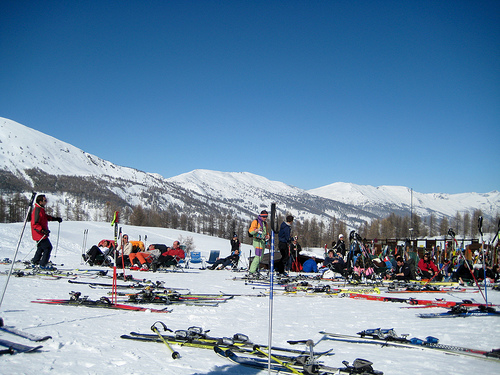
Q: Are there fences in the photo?
A: No, there are no fences.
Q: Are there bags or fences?
A: No, there are no fences or bags.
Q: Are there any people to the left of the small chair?
A: Yes, there is a person to the left of the chair.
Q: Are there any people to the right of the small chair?
A: No, the person is to the left of the chair.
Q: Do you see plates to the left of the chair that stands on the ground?
A: No, there is a person to the left of the chair.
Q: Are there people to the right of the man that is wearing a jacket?
A: Yes, there is a person to the right of the man.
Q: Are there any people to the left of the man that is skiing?
A: No, the person is to the right of the man.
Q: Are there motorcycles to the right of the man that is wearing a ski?
A: No, there is a person to the right of the man.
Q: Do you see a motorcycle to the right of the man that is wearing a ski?
A: No, there is a person to the right of the man.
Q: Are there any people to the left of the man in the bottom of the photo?
A: Yes, there is a person to the left of the man.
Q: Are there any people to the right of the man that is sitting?
A: No, the person is to the left of the man.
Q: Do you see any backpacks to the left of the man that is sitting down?
A: No, there is a person to the left of the man.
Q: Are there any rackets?
A: No, there are no rackets.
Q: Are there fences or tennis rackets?
A: No, there are no tennis rackets or fences.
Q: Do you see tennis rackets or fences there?
A: No, there are no tennis rackets or fences.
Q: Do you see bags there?
A: No, there are no bags.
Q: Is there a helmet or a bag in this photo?
A: No, there are no bags or helmets.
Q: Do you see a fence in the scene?
A: No, there are no fences.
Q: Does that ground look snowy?
A: Yes, the ground is snowy.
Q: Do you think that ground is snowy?
A: Yes, the ground is snowy.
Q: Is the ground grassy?
A: No, the ground is snowy.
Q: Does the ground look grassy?
A: No, the ground is snowy.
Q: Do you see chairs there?
A: Yes, there is a chair.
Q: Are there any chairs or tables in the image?
A: Yes, there is a chair.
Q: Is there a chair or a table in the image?
A: Yes, there is a chair.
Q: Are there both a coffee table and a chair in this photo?
A: No, there is a chair but no coffee tables.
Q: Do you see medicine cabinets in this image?
A: No, there are no medicine cabinets.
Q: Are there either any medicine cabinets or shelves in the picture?
A: No, there are no medicine cabinets or shelves.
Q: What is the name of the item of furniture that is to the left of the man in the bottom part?
A: The piece of furniture is a chair.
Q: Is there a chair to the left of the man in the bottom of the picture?
A: Yes, there is a chair to the left of the man.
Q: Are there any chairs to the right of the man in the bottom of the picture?
A: No, the chair is to the left of the man.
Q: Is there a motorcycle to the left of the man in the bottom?
A: No, there is a chair to the left of the man.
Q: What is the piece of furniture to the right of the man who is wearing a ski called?
A: The piece of furniture is a chair.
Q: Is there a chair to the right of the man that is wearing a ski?
A: Yes, there is a chair to the right of the man.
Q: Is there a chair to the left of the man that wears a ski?
A: No, the chair is to the right of the man.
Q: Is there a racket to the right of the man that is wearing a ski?
A: No, there is a chair to the right of the man.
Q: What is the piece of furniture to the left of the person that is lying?
A: The piece of furniture is a chair.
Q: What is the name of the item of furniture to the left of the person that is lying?
A: The piece of furniture is a chair.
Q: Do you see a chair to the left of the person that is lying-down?
A: Yes, there is a chair to the left of the person.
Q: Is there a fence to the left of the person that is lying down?
A: No, there is a chair to the left of the person.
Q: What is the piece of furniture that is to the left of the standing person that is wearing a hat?
A: The piece of furniture is a chair.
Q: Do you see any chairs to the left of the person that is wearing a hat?
A: Yes, there is a chair to the left of the person.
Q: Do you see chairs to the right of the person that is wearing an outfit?
A: No, the chair is to the left of the person.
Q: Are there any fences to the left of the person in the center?
A: No, there is a chair to the left of the person.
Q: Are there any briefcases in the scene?
A: No, there are no briefcases.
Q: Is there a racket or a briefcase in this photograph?
A: No, there are no briefcases or rackets.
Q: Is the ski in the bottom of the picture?
A: Yes, the ski is in the bottom of the image.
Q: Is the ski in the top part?
A: No, the ski is in the bottom of the image.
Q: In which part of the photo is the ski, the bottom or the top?
A: The ski is in the bottom of the image.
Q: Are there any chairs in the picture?
A: Yes, there is a chair.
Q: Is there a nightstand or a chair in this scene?
A: Yes, there is a chair.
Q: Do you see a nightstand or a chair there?
A: Yes, there is a chair.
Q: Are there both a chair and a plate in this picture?
A: No, there is a chair but no plates.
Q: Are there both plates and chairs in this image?
A: No, there is a chair but no plates.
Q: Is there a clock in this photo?
A: No, there are no clocks.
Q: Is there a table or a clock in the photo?
A: No, there are no clocks or tables.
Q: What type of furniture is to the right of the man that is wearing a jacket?
A: The piece of furniture is a chair.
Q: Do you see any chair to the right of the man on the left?
A: Yes, there is a chair to the right of the man.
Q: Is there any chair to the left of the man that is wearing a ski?
A: No, the chair is to the right of the man.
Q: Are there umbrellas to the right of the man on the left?
A: No, there is a chair to the right of the man.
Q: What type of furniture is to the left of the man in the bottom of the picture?
A: The piece of furniture is a chair.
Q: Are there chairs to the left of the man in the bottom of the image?
A: Yes, there is a chair to the left of the man.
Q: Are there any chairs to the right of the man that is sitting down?
A: No, the chair is to the left of the man.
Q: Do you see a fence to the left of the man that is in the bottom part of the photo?
A: No, there is a chair to the left of the man.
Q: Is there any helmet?
A: No, there are no helmets.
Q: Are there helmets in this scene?
A: No, there are no helmets.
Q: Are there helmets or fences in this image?
A: No, there are no helmets or fences.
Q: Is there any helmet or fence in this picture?
A: No, there are no helmets or fences.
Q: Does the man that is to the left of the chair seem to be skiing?
A: Yes, the man is skiing.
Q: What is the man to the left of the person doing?
A: The man is skiing.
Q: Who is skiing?
A: The man is skiing.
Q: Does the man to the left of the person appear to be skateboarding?
A: No, the man is skiing.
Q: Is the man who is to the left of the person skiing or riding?
A: The man is skiing.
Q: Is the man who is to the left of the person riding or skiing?
A: The man is skiing.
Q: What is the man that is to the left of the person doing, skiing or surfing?
A: The man is skiing.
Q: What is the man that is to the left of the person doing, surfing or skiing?
A: The man is skiing.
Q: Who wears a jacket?
A: The man wears a jacket.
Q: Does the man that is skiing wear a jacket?
A: Yes, the man wears a jacket.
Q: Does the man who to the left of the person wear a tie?
A: No, the man wears a jacket.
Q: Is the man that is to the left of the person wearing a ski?
A: Yes, the man is wearing a ski.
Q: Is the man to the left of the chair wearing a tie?
A: No, the man is wearing a ski.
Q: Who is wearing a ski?
A: The man is wearing a ski.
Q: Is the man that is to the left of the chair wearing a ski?
A: Yes, the man is wearing a ski.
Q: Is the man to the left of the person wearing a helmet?
A: No, the man is wearing a ski.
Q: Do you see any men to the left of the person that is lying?
A: Yes, there is a man to the left of the person.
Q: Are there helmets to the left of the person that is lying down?
A: No, there is a man to the left of the person.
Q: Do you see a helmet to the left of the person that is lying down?
A: No, there is a man to the left of the person.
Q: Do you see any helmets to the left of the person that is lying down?
A: No, there is a man to the left of the person.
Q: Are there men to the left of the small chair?
A: Yes, there is a man to the left of the chair.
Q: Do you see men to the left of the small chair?
A: Yes, there is a man to the left of the chair.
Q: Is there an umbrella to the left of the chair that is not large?
A: No, there is a man to the left of the chair.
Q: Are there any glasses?
A: No, there are no glasses.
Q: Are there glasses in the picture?
A: No, there are no glasses.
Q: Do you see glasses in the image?
A: No, there are no glasses.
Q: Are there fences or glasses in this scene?
A: No, there are no glasses or fences.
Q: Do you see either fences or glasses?
A: No, there are no glasses or fences.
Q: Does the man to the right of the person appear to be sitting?
A: Yes, the man is sitting.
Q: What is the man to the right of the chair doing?
A: The man is sitting.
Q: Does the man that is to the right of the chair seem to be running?
A: No, the man is sitting.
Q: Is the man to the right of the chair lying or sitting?
A: The man is sitting.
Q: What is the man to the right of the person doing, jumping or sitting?
A: The man is sitting.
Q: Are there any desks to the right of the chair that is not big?
A: No, there is a man to the right of the chair.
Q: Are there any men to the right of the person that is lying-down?
A: Yes, there is a man to the right of the person.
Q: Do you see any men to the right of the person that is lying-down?
A: Yes, there is a man to the right of the person.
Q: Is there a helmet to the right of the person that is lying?
A: No, there is a man to the right of the person.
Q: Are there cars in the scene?
A: No, there are no cars.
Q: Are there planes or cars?
A: No, there are no cars or planes.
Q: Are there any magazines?
A: No, there are no magazines.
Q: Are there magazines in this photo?
A: No, there are no magazines.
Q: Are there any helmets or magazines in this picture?
A: No, there are no magazines or helmets.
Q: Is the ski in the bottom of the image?
A: Yes, the ski is in the bottom of the image.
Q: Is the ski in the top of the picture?
A: No, the ski is in the bottom of the image.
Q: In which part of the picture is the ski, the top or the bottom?
A: The ski is in the bottom of the image.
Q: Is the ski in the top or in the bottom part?
A: The ski is in the bottom of the image.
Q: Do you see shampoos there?
A: No, there are no shampoos.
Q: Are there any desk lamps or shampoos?
A: No, there are no shampoos or desk lamps.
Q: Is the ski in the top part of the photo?
A: No, the ski is in the bottom of the image.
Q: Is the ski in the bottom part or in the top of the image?
A: The ski is in the bottom of the image.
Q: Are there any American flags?
A: No, there are no American flags.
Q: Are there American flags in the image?
A: No, there are no American flags.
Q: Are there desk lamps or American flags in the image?
A: No, there are no American flags or desk lamps.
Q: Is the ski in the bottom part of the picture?
A: Yes, the ski is in the bottom of the image.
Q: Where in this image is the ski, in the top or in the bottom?
A: The ski is in the bottom of the image.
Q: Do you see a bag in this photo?
A: No, there are no bags.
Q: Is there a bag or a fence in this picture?
A: No, there are no bags or fences.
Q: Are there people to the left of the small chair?
A: Yes, there is a person to the left of the chair.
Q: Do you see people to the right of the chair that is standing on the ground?
A: No, the person is to the left of the chair.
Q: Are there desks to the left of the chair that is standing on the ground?
A: No, there is a person to the left of the chair.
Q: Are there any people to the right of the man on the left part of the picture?
A: Yes, there is a person to the right of the man.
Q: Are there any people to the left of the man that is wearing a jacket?
A: No, the person is to the right of the man.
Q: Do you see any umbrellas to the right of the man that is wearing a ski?
A: No, there is a person to the right of the man.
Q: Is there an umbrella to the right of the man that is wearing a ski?
A: No, there is a person to the right of the man.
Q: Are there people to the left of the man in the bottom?
A: Yes, there is a person to the left of the man.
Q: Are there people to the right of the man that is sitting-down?
A: No, the person is to the left of the man.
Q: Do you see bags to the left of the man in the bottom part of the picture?
A: No, there is a person to the left of the man.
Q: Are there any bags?
A: No, there are no bags.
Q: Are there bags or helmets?
A: No, there are no bags or helmets.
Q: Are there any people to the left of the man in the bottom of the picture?
A: Yes, there is a person to the left of the man.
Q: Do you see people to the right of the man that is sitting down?
A: No, the person is to the left of the man.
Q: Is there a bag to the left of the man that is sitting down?
A: No, there is a person to the left of the man.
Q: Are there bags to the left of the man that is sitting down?
A: No, there is a person to the left of the man.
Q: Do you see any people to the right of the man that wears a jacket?
A: Yes, there is a person to the right of the man.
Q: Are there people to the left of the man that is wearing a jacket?
A: No, the person is to the right of the man.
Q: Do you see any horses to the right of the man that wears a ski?
A: No, there is a person to the right of the man.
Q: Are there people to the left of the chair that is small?
A: Yes, there is a person to the left of the chair.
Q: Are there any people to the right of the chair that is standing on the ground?
A: No, the person is to the left of the chair.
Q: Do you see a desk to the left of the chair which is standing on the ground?
A: No, there is a person to the left of the chair.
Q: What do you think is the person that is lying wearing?
A: The person is wearing a jacket.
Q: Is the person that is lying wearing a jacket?
A: Yes, the person is wearing a jacket.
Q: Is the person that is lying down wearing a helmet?
A: No, the person is wearing a jacket.